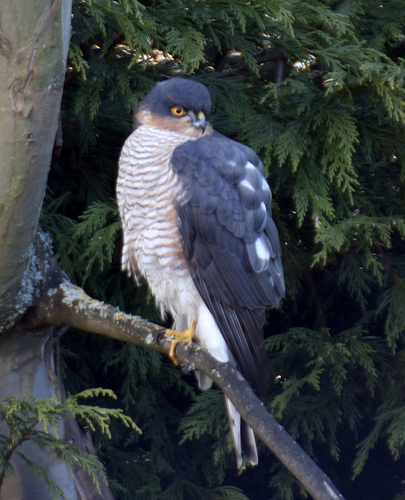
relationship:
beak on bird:
[192, 111, 207, 130] [111, 71, 309, 394]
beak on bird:
[194, 110, 207, 134] [111, 71, 309, 394]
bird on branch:
[111, 71, 309, 394] [33, 224, 349, 498]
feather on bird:
[227, 396, 263, 467] [111, 71, 309, 394]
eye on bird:
[168, 103, 185, 120] [120, 60, 315, 448]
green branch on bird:
[0, 385, 138, 498] [111, 71, 309, 394]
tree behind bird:
[224, 14, 398, 153] [111, 71, 309, 394]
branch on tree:
[33, 224, 349, 498] [224, 14, 398, 153]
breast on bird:
[117, 150, 201, 246] [93, 77, 344, 351]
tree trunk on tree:
[1, 4, 53, 315] [224, 14, 398, 153]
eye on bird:
[172, 103, 188, 120] [116, 63, 338, 395]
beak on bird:
[186, 104, 211, 134] [111, 71, 309, 394]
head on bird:
[135, 64, 242, 154] [111, 71, 309, 394]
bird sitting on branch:
[111, 71, 309, 394] [33, 224, 349, 498]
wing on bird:
[172, 126, 288, 313] [111, 71, 309, 394]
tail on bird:
[225, 400, 260, 475] [111, 71, 309, 394]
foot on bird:
[159, 320, 207, 363] [111, 71, 309, 394]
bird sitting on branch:
[111, 71, 309, 394] [64, 282, 340, 483]